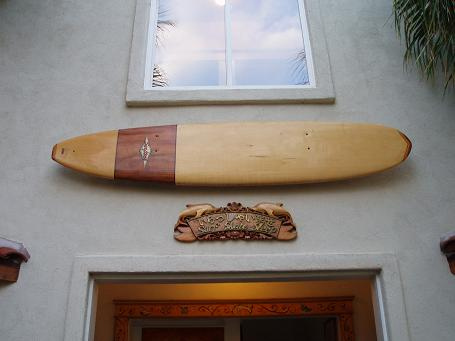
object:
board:
[52, 122, 412, 187]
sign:
[173, 202, 297, 243]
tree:
[394, 0, 453, 101]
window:
[124, 0, 335, 107]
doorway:
[75, 261, 391, 341]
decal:
[139, 137, 152, 168]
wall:
[0, 0, 443, 341]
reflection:
[153, 14, 302, 89]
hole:
[307, 147, 310, 150]